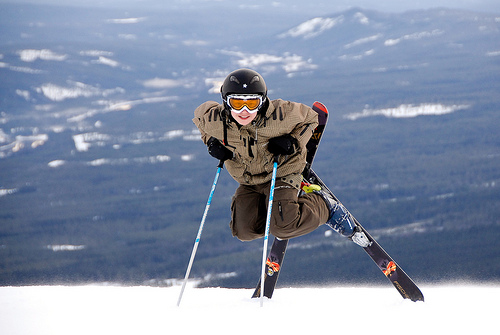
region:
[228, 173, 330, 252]
grey colored ski pants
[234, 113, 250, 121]
smile on a person's face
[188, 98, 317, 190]
a person's brown colored jacket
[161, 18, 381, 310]
woman wearing skis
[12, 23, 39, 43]
white clouds in blue sky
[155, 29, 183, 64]
white clouds in blue sky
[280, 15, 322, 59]
white clouds in blue sky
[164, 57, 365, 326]
skier in white snow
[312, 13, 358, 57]
white clouds in blue sky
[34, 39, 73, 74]
white clouds in blue sky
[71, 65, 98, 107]
white clouds in blue sky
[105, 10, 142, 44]
white clouds in blue sky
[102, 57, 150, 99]
white clouds in blue sky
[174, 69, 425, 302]
skier balancing on skis and poles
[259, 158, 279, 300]
a skier's left ski pole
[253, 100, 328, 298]
a skier's right ski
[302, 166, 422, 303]
a skier's left ski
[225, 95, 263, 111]
a skier's ski goggles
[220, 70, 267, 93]
a skier's ski helmet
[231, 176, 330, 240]
a skier's brown ski pants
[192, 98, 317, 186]
a skier's brown ski jacket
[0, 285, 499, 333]
snow covered ground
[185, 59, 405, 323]
woman on snowy hill side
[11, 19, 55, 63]
white clouds in blue sky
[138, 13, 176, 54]
white clouds in blue sky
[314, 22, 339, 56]
white clouds in blue sky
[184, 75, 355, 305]
skier on snowy slope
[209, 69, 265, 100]
The black helmet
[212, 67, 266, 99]
A black helmet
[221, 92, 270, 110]
The orange goggles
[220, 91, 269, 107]
A pair of orange goggles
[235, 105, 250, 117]
The nose on the skier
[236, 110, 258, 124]
A mouth on the skier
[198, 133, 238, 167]
The left gloved hand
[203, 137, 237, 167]
A gloved left hand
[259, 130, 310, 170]
The gloved right hand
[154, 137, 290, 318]
a pair of poles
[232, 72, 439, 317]
a pair of skis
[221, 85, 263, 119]
an orange goggle set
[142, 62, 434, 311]
woman leaning on poles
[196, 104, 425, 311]
woman has feet crossed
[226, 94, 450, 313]
pair of skis are crossed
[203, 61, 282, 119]
a matte black helmet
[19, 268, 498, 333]
snow on the ground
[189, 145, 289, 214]
blue trim on poles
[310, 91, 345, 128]
red tip of ski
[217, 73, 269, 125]
black helmet over the head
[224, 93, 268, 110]
orage and silver glasses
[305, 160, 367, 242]
blue ski boot right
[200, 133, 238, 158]
left black glove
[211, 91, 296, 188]
woman with brown jacket